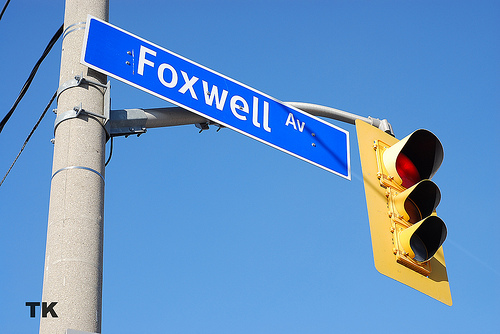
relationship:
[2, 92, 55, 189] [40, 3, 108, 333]
utility lines running to pole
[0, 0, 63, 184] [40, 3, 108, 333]
utility lines running to pole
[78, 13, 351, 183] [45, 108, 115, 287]
foxwell av on pole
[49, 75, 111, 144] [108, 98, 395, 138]
brackets of arm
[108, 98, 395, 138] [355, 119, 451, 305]
arm holding traffic light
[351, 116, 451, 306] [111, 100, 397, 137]
stop light on a pole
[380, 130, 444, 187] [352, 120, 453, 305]
red light on a traffic signal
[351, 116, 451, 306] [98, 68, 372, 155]
stop light on a pole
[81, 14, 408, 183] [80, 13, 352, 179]
foxwell av on a street sign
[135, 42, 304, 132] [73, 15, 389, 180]
street name on a sign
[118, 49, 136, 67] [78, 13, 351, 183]
bolts on a foxwell av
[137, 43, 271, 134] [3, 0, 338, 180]
foxwell on a sign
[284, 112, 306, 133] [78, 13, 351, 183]
abbreviation on a foxwell av